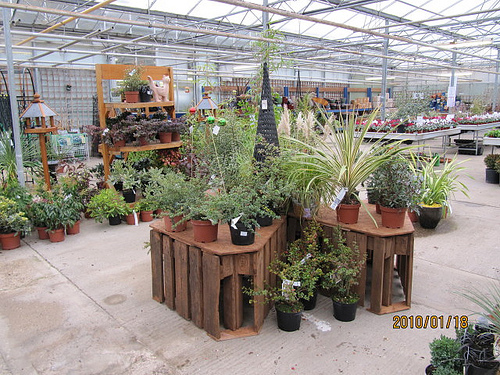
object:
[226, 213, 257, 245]
pot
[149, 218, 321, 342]
stand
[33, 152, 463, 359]
floor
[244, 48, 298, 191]
cones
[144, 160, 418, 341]
tables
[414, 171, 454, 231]
pot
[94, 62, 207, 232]
shelves